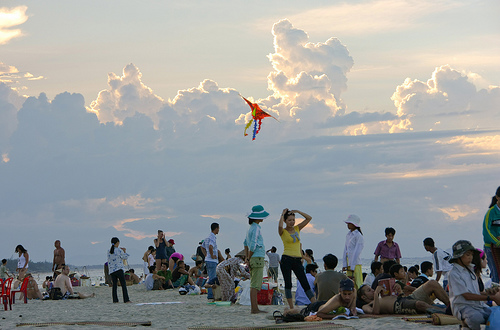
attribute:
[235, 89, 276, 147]
kite — flying, colorful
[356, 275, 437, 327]
guy — reading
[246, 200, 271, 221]
hat — green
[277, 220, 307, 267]
teeshirt — yellow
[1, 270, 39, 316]
chairs — red